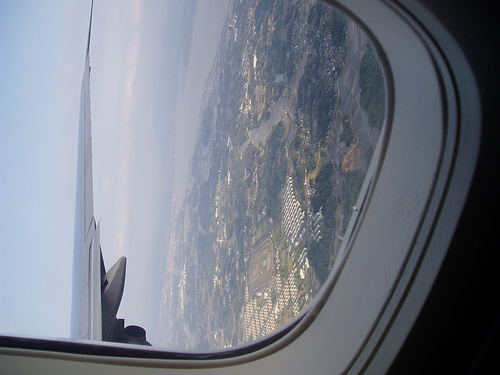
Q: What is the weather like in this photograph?
A: It is cloudy.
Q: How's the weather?
A: It is cloudy.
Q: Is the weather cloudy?
A: Yes, it is cloudy.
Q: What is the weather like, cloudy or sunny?
A: It is cloudy.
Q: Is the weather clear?
A: No, it is cloudy.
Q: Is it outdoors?
A: Yes, it is outdoors.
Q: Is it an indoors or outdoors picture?
A: It is outdoors.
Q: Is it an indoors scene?
A: No, it is outdoors.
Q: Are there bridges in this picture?
A: No, there are no bridges.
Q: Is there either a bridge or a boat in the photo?
A: No, there are no bridges or boats.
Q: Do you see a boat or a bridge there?
A: No, there are no bridges or boats.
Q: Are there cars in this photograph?
A: No, there are no cars.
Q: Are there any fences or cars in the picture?
A: No, there are no cars or fences.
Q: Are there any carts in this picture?
A: No, there are no carts.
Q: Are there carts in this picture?
A: No, there are no carts.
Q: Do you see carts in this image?
A: No, there are no carts.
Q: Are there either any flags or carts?
A: No, there are no carts or flags.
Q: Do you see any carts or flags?
A: No, there are no carts or flags.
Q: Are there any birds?
A: No, there are no birds.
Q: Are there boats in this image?
A: No, there are no boats.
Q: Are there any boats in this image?
A: No, there are no boats.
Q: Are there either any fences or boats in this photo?
A: No, there are no boats or fences.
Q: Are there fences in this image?
A: No, there are no fences.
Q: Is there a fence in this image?
A: No, there are no fences.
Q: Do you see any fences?
A: No, there are no fences.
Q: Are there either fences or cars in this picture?
A: No, there are no fences or cars.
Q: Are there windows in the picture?
A: Yes, there is a window.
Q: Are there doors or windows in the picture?
A: Yes, there is a window.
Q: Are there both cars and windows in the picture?
A: No, there is a window but no cars.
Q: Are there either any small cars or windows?
A: Yes, there is a small window.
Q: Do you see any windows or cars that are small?
A: Yes, the window is small.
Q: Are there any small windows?
A: Yes, there is a small window.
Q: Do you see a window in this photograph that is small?
A: Yes, there is a window that is small.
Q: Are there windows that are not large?
A: Yes, there is a small window.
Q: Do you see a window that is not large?
A: Yes, there is a small window.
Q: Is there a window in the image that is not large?
A: Yes, there is a small window.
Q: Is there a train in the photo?
A: No, there are no trains.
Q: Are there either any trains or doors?
A: No, there are no trains or doors.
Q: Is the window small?
A: Yes, the window is small.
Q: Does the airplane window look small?
A: Yes, the window is small.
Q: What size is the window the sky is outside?
A: The window is small.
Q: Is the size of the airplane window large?
A: No, the window is small.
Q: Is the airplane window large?
A: No, the window is small.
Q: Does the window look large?
A: No, the window is small.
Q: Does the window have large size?
A: No, the window is small.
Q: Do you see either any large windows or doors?
A: No, there is a window but it is small.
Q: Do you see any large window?
A: No, there is a window but it is small.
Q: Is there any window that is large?
A: No, there is a window but it is small.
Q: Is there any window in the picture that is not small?
A: No, there is a window but it is small.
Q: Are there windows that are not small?
A: No, there is a window but it is small.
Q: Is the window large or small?
A: The window is small.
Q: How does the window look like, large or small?
A: The window is small.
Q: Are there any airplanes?
A: Yes, there is an airplane.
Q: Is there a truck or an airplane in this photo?
A: Yes, there is an airplane.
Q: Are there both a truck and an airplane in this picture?
A: No, there is an airplane but no trucks.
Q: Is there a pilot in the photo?
A: No, there are no pilots.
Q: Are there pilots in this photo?
A: No, there are no pilots.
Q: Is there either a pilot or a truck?
A: No, there are no pilots or trucks.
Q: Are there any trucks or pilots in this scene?
A: No, there are no pilots or trucks.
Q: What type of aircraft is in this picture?
A: The aircraft is an airplane.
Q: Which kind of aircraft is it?
A: The aircraft is an airplane.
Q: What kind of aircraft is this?
A: This is an airplane.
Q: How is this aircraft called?
A: This is an airplane.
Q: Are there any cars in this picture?
A: No, there are no cars.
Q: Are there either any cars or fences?
A: No, there are no cars or fences.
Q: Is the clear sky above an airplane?
A: Yes, the sky is above an airplane.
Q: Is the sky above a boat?
A: No, the sky is above an airplane.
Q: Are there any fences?
A: No, there are no fences.